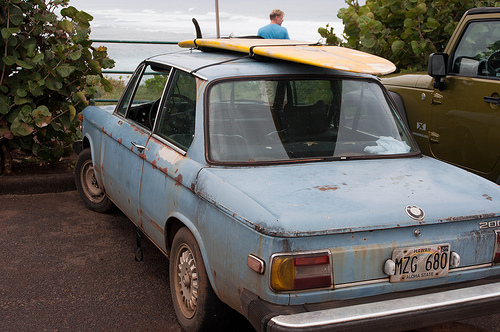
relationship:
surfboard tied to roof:
[175, 30, 399, 74] [184, 52, 245, 72]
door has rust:
[109, 113, 145, 208] [105, 124, 145, 157]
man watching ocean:
[252, 7, 296, 44] [120, 12, 152, 35]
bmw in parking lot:
[68, 44, 499, 332] [34, 228, 97, 289]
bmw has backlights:
[68, 44, 499, 332] [268, 251, 341, 295]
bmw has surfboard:
[68, 44, 499, 332] [175, 30, 399, 74]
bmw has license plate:
[68, 44, 499, 332] [390, 241, 452, 285]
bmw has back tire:
[68, 44, 499, 332] [159, 222, 210, 331]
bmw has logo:
[68, 44, 499, 332] [401, 198, 431, 226]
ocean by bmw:
[120, 12, 152, 35] [68, 44, 499, 332]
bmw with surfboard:
[68, 44, 499, 332] [175, 30, 399, 74]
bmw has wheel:
[68, 44, 499, 332] [149, 93, 158, 127]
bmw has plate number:
[68, 44, 499, 332] [393, 253, 447, 274]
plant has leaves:
[17, 17, 65, 98] [64, 9, 94, 36]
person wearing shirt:
[252, 7, 296, 44] [253, 25, 293, 40]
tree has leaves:
[352, 6, 431, 49] [64, 9, 94, 36]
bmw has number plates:
[68, 44, 499, 332] [471, 215, 499, 232]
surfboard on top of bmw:
[175, 30, 399, 74] [68, 44, 499, 332]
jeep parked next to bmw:
[409, 0, 499, 158] [68, 44, 499, 332]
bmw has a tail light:
[68, 44, 499, 332] [487, 225, 499, 273]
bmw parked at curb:
[68, 44, 499, 332] [15, 171, 54, 196]